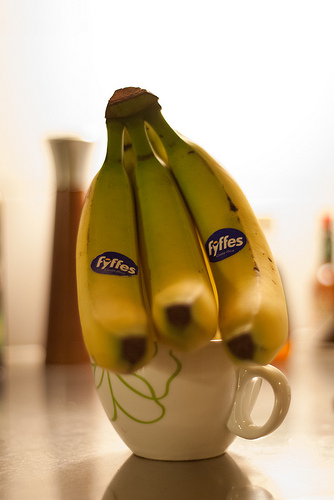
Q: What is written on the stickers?
A: Fyffes.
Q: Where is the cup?
A: Under the bananas.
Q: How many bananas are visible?
A: 3.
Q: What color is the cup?
A: White.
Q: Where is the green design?
A: On the cup.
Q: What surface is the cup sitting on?
A: Table.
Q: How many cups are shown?
A: 1.